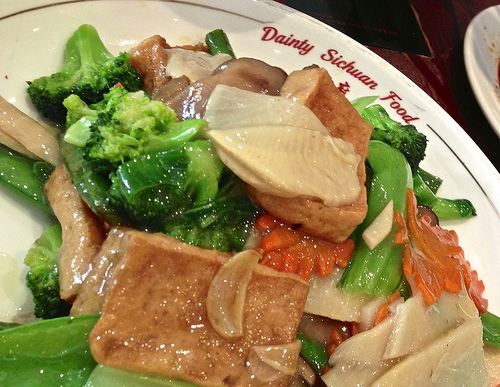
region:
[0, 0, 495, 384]
a plate filled with assorte meat and veggies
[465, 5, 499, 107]
another plate sitting on the table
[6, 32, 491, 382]
the food covered up in sauce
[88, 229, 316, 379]
a big chunk of meat on the plate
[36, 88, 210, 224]
some cut up green veggies on the plate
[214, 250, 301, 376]
little pieces of garlic on the meat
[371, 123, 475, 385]
colorful veggies on the side of the plate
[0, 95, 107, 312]
some more slices of meat on the plate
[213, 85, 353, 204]
something lying on top of the meat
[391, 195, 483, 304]
the food shaped like a leaf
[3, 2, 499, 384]
food in a white dish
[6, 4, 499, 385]
dish has a line on the border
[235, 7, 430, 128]
letters on side a dish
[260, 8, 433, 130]
red letters on border of dish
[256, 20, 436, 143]
letters says "Dainty Sichuan Food"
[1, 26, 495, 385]
green vegetables with meat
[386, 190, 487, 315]
slices of carrots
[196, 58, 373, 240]
white meat with sauce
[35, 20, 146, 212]
green broccoli on white dish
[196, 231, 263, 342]
slice of garlic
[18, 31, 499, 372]
sichuan food on plate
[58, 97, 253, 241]
broccoli on plate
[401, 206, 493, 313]
carrots on plate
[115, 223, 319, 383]
chicken on plate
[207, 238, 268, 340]
cashew on plate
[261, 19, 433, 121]
Dainty Sichuan Food written on plate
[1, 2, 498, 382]
plate is round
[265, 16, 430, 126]
red lettering on plate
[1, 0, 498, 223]
brown stripe on edge of plate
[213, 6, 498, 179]
plate sitting on red tablecloth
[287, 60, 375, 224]
the tofu is brown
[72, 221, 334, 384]
the tofu is brown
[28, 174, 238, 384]
the tofu is brown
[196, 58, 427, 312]
the tofu is brown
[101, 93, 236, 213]
the broccoli is green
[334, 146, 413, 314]
the broccoli is green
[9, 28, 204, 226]
the broccoli is green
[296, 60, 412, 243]
the broccoli is green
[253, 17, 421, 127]
restaurant name on plate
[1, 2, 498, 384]
plate which contains food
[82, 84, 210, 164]
broccoli spear mingled with rest of foot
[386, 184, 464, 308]
carrot slices like a leaf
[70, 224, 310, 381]
chicken piece mingled with rest of food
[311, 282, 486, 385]
pasta mingled with rest of food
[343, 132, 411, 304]
green bean mingled with rest of food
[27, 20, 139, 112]
broccoli spear mingled with rest of food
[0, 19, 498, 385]
food on a plate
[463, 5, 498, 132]
edge of another white plate